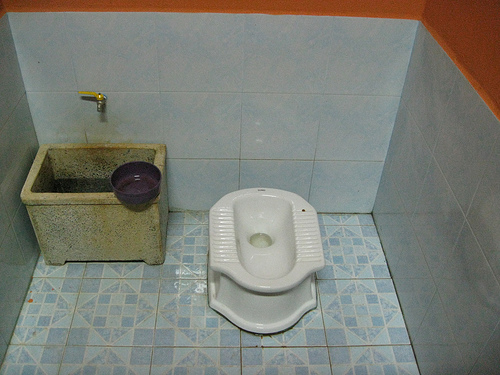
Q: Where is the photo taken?
A: Bathroom.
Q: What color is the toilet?
A: White.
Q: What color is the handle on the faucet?
A: Yellow.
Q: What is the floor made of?
A: Tile.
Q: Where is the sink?
A: Left corner.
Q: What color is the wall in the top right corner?
A: Orange.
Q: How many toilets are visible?
A: One.